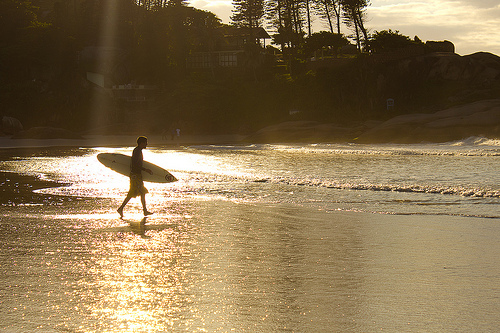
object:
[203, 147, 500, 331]
ocean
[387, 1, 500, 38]
sky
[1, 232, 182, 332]
ocean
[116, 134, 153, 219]
surfer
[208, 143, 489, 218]
water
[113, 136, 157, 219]
person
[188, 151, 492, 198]
waves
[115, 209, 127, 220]
feet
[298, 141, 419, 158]
sunlight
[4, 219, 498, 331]
beach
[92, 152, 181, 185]
surfboard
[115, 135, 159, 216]
man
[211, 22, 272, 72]
house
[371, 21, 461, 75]
outcropping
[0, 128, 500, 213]
beach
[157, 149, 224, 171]
sun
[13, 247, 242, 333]
water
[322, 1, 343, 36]
trees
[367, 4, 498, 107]
hill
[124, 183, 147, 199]
shorts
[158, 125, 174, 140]
people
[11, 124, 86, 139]
rocks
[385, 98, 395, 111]
sign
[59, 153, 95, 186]
ray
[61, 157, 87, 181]
sunshine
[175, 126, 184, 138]
person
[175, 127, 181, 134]
shirt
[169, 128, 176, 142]
people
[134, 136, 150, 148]
head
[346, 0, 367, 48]
tree